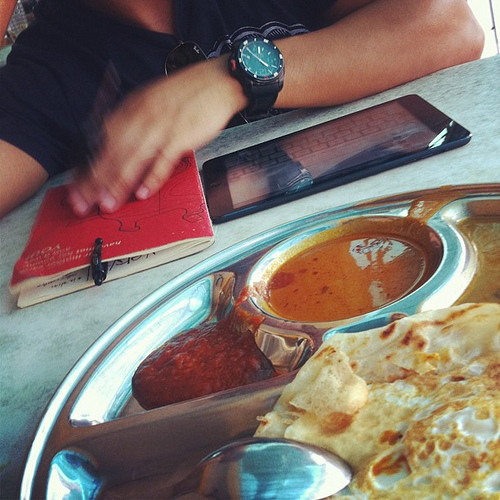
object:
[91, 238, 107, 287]
pen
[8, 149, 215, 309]
notebook